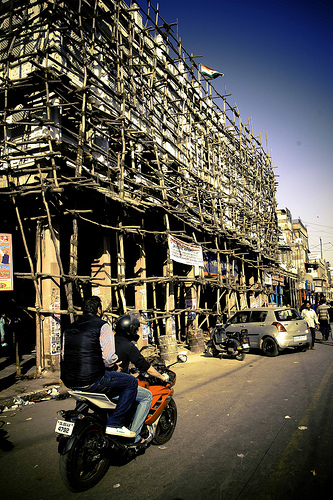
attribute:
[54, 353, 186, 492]
motorcycle — red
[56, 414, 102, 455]
rear fender — black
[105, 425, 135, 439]
sneaker — white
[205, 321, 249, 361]
motorcycle — parked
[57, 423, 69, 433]
lettering — black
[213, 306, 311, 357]
vehicle — small, gray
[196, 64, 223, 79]
mexican flag — large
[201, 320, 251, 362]
scooter — dusty, black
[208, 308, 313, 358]
suv — small, silver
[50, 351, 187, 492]
bike — red, black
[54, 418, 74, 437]
license plate — white, small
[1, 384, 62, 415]
curb — littered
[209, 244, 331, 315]
poles — colorful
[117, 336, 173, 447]
bike — red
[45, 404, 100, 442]
plate — small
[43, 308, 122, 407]
vest — black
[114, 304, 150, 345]
helmet — black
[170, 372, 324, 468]
road — dirty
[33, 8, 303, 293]
building — large